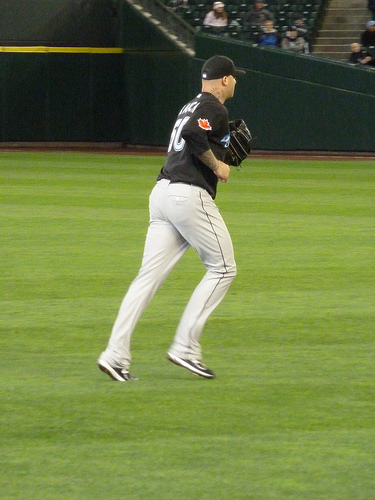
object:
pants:
[105, 177, 238, 369]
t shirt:
[157, 91, 230, 200]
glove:
[225, 119, 257, 171]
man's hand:
[225, 118, 252, 166]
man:
[96, 55, 253, 383]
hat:
[201, 55, 247, 80]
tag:
[197, 118, 213, 131]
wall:
[0, 0, 375, 153]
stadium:
[1, 0, 372, 497]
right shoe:
[167, 342, 214, 378]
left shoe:
[97, 351, 139, 383]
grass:
[0, 148, 375, 500]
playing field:
[1, 145, 373, 500]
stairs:
[134, 0, 198, 60]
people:
[202, 1, 375, 67]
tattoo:
[210, 86, 225, 101]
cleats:
[97, 348, 215, 382]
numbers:
[168, 116, 191, 152]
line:
[0, 45, 125, 55]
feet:
[97, 345, 215, 381]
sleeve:
[181, 100, 222, 156]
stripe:
[188, 190, 227, 351]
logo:
[202, 73, 206, 78]